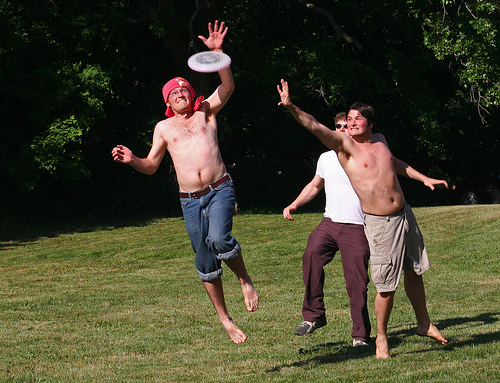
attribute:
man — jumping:
[132, 80, 271, 268]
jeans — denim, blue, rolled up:
[173, 177, 284, 299]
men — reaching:
[271, 90, 433, 332]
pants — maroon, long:
[285, 218, 401, 343]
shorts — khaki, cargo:
[333, 210, 472, 340]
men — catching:
[135, 84, 489, 304]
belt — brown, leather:
[171, 171, 242, 203]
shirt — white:
[310, 139, 367, 223]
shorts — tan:
[357, 207, 437, 294]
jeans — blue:
[163, 170, 247, 287]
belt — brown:
[174, 174, 244, 200]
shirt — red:
[153, 72, 205, 118]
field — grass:
[16, 251, 168, 381]